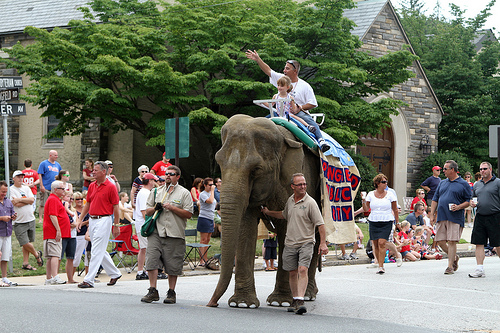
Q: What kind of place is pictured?
A: It is a road.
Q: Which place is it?
A: It is a road.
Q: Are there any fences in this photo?
A: No, there are no fences.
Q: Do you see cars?
A: No, there are no cars.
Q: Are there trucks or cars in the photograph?
A: No, there are no cars or trucks.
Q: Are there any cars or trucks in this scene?
A: No, there are no cars or trucks.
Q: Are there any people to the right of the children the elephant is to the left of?
A: Yes, there are people to the right of the children.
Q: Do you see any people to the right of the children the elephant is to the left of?
A: Yes, there are people to the right of the children.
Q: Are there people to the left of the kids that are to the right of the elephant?
A: No, the people are to the right of the kids.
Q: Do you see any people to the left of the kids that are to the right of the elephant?
A: No, the people are to the right of the kids.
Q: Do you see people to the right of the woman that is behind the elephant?
A: Yes, there are people to the right of the woman.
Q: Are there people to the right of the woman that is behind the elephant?
A: Yes, there are people to the right of the woman.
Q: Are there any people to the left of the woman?
A: No, the people are to the right of the woman.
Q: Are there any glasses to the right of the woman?
A: No, there are people to the right of the woman.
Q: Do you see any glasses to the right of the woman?
A: No, there are people to the right of the woman.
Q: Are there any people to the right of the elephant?
A: Yes, there are people to the right of the elephant.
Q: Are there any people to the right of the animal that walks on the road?
A: Yes, there are people to the right of the elephant.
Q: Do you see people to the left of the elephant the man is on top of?
A: No, the people are to the right of the elephant.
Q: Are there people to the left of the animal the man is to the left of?
A: No, the people are to the right of the elephant.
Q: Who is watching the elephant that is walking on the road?
A: The people are watching the elephant.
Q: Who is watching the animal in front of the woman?
A: The people are watching the elephant.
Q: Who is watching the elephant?
A: The people are watching the elephant.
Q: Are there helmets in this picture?
A: No, there are no helmets.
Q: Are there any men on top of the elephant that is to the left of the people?
A: Yes, there is a man on top of the elephant.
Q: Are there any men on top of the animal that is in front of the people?
A: Yes, there is a man on top of the elephant.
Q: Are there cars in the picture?
A: No, there are no cars.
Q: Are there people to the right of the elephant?
A: Yes, there are people to the right of the elephant.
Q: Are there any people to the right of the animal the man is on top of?
A: Yes, there are people to the right of the elephant.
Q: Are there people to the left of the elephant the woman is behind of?
A: No, the people are to the right of the elephant.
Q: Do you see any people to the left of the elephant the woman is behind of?
A: No, the people are to the right of the elephant.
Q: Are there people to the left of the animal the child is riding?
A: No, the people are to the right of the elephant.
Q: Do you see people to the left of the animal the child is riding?
A: No, the people are to the right of the elephant.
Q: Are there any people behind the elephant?
A: Yes, there are people behind the elephant.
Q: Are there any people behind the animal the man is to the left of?
A: Yes, there are people behind the elephant.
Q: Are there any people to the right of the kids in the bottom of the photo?
A: Yes, there are people to the right of the children.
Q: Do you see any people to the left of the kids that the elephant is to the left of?
A: No, the people are to the right of the kids.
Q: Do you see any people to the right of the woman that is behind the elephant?
A: Yes, there are people to the right of the woman.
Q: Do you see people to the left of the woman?
A: No, the people are to the right of the woman.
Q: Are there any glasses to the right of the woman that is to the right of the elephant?
A: No, there are people to the right of the woman.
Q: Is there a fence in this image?
A: No, there are no fences.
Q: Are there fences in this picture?
A: No, there are no fences.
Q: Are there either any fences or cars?
A: No, there are no fences or cars.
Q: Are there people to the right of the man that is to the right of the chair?
A: Yes, there is a person to the right of the man.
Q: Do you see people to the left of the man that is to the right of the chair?
A: No, the person is to the right of the man.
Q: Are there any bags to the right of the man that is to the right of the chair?
A: No, there is a person to the right of the man.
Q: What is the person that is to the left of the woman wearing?
A: The person is wearing a shirt.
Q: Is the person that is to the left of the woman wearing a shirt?
A: Yes, the person is wearing a shirt.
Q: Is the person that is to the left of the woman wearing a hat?
A: No, the person is wearing a shirt.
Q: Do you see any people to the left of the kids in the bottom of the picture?
A: Yes, there is a person to the left of the children.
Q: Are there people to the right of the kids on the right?
A: No, the person is to the left of the kids.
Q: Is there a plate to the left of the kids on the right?
A: No, there is a person to the left of the children.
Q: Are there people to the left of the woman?
A: Yes, there is a person to the left of the woman.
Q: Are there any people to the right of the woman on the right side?
A: No, the person is to the left of the woman.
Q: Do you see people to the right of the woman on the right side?
A: No, the person is to the left of the woman.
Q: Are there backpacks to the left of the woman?
A: No, there is a person to the left of the woman.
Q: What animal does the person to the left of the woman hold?
A: The person holds the elephant.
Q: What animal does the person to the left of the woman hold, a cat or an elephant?
A: The person holds an elephant.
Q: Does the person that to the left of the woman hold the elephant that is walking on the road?
A: Yes, the person holds the elephant.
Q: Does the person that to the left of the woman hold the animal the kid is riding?
A: Yes, the person holds the elephant.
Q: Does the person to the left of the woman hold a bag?
A: No, the person holds the elephant.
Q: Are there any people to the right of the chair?
A: Yes, there is a person to the right of the chair.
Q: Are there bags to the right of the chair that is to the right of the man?
A: No, there is a person to the right of the chair.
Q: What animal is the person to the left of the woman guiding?
A: The person is guiding the elephant.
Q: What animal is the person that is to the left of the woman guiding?
A: The person is guiding the elephant.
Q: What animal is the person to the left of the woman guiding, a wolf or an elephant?
A: The person is guiding an elephant.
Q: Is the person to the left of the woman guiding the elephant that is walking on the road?
A: Yes, the person is guiding the elephant.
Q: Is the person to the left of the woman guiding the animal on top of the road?
A: Yes, the person is guiding the elephant.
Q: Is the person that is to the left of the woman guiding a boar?
A: No, the person is guiding the elephant.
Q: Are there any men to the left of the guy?
A: Yes, there is a man to the left of the guy.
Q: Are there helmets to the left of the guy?
A: No, there is a man to the left of the guy.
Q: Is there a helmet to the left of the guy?
A: No, there is a man to the left of the guy.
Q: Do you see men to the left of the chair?
A: Yes, there is a man to the left of the chair.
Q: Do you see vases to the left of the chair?
A: No, there is a man to the left of the chair.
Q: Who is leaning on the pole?
A: The man is leaning on the pole.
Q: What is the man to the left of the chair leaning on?
A: The man is leaning on the pole.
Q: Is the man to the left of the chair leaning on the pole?
A: Yes, the man is leaning on the pole.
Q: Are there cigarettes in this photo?
A: No, there are no cigarettes.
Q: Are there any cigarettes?
A: No, there are no cigarettes.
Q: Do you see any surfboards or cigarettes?
A: No, there are no cigarettes or surfboards.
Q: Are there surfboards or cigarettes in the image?
A: No, there are no cigarettes or surfboards.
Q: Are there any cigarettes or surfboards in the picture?
A: No, there are no cigarettes or surfboards.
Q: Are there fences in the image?
A: No, there are no fences.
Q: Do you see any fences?
A: No, there are no fences.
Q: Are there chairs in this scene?
A: Yes, there is a chair.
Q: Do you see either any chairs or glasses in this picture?
A: Yes, there is a chair.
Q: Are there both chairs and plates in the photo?
A: No, there is a chair but no plates.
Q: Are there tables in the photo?
A: No, there are no tables.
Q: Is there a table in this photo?
A: No, there are no tables.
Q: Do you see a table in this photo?
A: No, there are no tables.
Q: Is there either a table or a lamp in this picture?
A: No, there are no tables or lamps.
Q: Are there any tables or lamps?
A: No, there are no tables or lamps.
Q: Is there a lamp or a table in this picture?
A: No, there are no tables or lamps.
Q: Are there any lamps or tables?
A: No, there are no tables or lamps.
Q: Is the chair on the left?
A: Yes, the chair is on the left of the image.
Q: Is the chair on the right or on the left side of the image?
A: The chair is on the left of the image.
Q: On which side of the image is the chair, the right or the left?
A: The chair is on the left of the image.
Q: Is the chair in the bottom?
A: Yes, the chair is in the bottom of the image.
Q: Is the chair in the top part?
A: No, the chair is in the bottom of the image.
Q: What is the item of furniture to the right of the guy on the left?
A: The piece of furniture is a chair.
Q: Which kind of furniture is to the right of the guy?
A: The piece of furniture is a chair.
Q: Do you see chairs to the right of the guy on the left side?
A: Yes, there is a chair to the right of the guy.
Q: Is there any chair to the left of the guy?
A: No, the chair is to the right of the guy.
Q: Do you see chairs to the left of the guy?
A: No, the chair is to the right of the guy.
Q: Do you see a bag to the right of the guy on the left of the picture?
A: No, there is a chair to the right of the guy.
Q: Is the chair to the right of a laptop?
A: No, the chair is to the right of the guy.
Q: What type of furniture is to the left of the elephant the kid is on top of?
A: The piece of furniture is a chair.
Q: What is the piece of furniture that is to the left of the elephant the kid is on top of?
A: The piece of furniture is a chair.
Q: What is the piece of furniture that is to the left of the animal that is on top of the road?
A: The piece of furniture is a chair.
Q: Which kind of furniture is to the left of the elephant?
A: The piece of furniture is a chair.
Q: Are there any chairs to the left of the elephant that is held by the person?
A: Yes, there is a chair to the left of the elephant.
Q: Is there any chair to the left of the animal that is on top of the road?
A: Yes, there is a chair to the left of the elephant.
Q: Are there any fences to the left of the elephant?
A: No, there is a chair to the left of the elephant.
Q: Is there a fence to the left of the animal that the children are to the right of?
A: No, there is a chair to the left of the elephant.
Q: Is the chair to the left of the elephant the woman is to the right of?
A: Yes, the chair is to the left of the elephant.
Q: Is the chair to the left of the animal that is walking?
A: Yes, the chair is to the left of the elephant.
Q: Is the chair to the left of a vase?
A: No, the chair is to the left of the elephant.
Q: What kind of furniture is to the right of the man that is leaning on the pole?
A: The piece of furniture is a chair.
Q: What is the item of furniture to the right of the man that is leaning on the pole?
A: The piece of furniture is a chair.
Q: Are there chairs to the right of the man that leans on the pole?
A: Yes, there is a chair to the right of the man.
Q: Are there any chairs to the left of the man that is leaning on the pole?
A: No, the chair is to the right of the man.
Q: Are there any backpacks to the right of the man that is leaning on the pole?
A: No, there is a chair to the right of the man.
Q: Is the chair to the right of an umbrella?
A: No, the chair is to the right of a man.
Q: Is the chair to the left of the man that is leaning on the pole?
A: No, the chair is to the right of the man.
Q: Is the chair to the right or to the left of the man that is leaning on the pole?
A: The chair is to the right of the man.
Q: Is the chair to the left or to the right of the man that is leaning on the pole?
A: The chair is to the right of the man.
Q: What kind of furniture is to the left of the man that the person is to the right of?
A: The piece of furniture is a chair.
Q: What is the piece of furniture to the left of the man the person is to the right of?
A: The piece of furniture is a chair.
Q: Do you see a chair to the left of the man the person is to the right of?
A: Yes, there is a chair to the left of the man.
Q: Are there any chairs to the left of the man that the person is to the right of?
A: Yes, there is a chair to the left of the man.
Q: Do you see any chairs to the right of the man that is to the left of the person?
A: No, the chair is to the left of the man.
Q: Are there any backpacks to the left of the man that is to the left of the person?
A: No, there is a chair to the left of the man.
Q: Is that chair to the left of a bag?
A: No, the chair is to the left of a man.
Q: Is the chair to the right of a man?
A: No, the chair is to the left of a man.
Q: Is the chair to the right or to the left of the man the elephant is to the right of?
A: The chair is to the left of the man.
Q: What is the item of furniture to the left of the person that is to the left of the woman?
A: The piece of furniture is a chair.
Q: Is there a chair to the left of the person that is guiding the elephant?
A: Yes, there is a chair to the left of the person.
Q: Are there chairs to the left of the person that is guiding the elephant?
A: Yes, there is a chair to the left of the person.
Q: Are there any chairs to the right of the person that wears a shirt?
A: No, the chair is to the left of the person.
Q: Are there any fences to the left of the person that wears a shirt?
A: No, there is a chair to the left of the person.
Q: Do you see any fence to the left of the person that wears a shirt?
A: No, there is a chair to the left of the person.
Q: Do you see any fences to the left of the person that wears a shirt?
A: No, there is a chair to the left of the person.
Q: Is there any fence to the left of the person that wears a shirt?
A: No, there is a chair to the left of the person.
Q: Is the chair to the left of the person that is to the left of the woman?
A: Yes, the chair is to the left of the person.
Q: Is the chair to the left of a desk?
A: No, the chair is to the left of the person.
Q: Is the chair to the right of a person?
A: No, the chair is to the left of a person.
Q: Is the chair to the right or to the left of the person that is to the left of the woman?
A: The chair is to the left of the person.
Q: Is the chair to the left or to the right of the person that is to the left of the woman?
A: The chair is to the left of the person.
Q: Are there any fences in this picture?
A: No, there are no fences.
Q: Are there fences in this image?
A: No, there are no fences.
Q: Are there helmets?
A: No, there are no helmets.